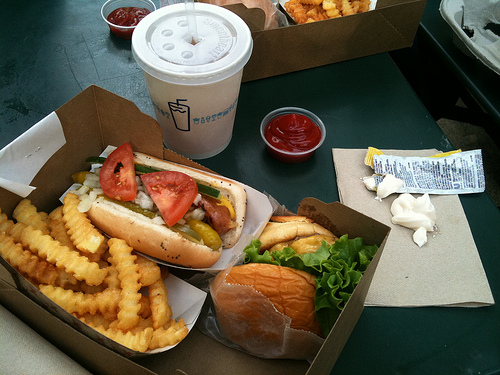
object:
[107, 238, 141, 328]
fry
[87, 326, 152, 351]
fry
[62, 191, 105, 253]
fry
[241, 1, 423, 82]
box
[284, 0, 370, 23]
food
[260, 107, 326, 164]
cup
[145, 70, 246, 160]
cup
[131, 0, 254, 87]
cover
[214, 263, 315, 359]
bun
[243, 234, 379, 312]
lettuce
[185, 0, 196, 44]
straw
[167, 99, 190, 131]
drawing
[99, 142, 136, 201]
tomato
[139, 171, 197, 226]
tomato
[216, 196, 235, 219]
mustard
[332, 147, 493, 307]
napkin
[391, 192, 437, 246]
mayo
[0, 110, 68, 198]
receipt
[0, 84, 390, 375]
box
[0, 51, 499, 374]
table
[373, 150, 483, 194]
mayonaisse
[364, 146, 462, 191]
mustard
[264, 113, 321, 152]
ketchup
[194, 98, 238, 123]
writing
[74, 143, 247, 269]
dog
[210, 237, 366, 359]
hamburger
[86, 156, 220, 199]
pickle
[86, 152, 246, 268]
bun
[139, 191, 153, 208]
onion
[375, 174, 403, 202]
sauce